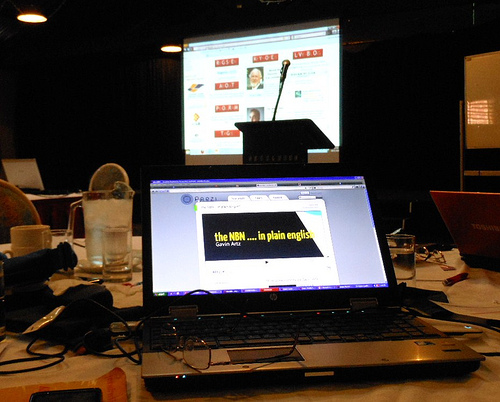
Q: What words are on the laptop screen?
A: The nbn in plain english.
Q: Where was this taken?
A: Conference.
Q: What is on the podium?
A: Microphone.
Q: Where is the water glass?
A: To the left of the laptop.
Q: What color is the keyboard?
A: Black.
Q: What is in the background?
A: Screen.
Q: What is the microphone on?
A: Podium.